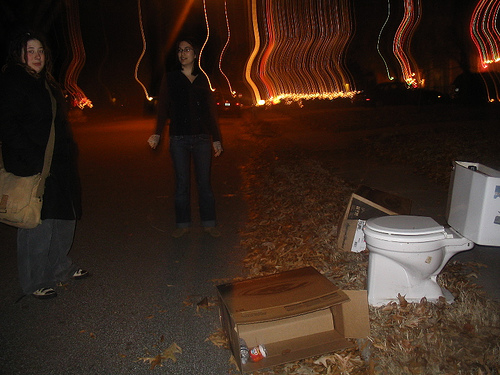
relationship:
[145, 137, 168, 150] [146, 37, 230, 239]
right hand on woman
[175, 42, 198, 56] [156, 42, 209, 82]
glasses on head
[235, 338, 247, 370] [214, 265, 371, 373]
bottle in box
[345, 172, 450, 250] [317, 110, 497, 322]
seat lid on toilet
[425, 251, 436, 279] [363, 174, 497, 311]
spot on toilet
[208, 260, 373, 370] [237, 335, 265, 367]
cardboard box with trash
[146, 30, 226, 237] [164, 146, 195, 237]
woman wearing jeans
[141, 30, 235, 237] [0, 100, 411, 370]
woman standing in road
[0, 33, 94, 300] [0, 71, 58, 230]
person carrying bag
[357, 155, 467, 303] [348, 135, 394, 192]
toilet attached ground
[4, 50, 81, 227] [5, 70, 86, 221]
person wearing coat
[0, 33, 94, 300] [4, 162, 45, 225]
person holding bag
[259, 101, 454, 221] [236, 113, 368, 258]
sidewalks sitting upong roadside